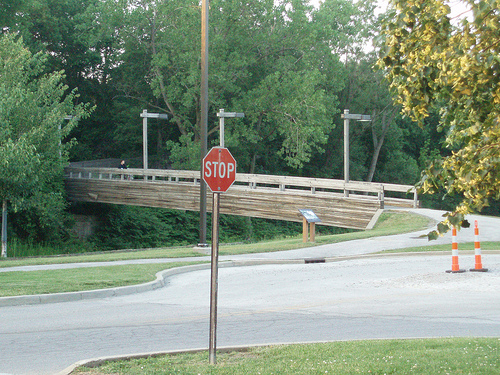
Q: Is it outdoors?
A: Yes, it is outdoors.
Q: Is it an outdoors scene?
A: Yes, it is outdoors.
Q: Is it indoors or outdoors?
A: It is outdoors.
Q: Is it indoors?
A: No, it is outdoors.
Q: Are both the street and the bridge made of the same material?
A: No, the street is made of concrete and the bridge is made of wood.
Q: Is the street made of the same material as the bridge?
A: No, the street is made of concrete and the bridge is made of wood.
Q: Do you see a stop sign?
A: Yes, there is a stop sign.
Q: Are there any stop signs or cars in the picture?
A: Yes, there is a stop sign.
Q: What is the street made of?
A: The street is made of cement.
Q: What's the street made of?
A: The street is made of concrete.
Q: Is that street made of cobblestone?
A: No, the street is made of concrete.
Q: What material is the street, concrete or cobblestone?
A: The street is made of concrete.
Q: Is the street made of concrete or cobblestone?
A: The street is made of concrete.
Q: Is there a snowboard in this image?
A: No, there are no snowboards.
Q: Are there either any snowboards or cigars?
A: No, there are no snowboards or cigars.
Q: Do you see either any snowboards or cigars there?
A: No, there are no snowboards or cigars.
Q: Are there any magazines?
A: No, there are no magazines.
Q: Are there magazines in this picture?
A: No, there are no magazines.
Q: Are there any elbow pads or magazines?
A: No, there are no magazines or elbow pads.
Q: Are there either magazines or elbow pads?
A: No, there are no magazines or elbow pads.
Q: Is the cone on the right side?
A: Yes, the cone is on the right of the image.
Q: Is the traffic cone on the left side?
A: No, the traffic cone is on the right of the image.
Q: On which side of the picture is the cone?
A: The cone is on the right of the image.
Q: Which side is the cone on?
A: The cone is on the right of the image.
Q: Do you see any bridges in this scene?
A: Yes, there is a bridge.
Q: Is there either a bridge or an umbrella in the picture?
A: Yes, there is a bridge.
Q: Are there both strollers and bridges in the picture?
A: No, there is a bridge but no strollers.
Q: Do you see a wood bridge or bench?
A: Yes, there is a wood bridge.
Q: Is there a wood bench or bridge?
A: Yes, there is a wood bridge.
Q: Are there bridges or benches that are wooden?
A: Yes, the bridge is wooden.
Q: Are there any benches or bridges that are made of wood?
A: Yes, the bridge is made of wood.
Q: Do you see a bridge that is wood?
A: Yes, there is a wood bridge.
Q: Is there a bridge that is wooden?
A: Yes, there is a bridge that is wooden.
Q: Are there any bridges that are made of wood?
A: Yes, there is a bridge that is made of wood.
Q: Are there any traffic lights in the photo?
A: No, there are no traffic lights.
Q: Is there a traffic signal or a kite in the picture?
A: No, there are no traffic lights or kites.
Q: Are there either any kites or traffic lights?
A: No, there are no traffic lights or kites.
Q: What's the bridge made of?
A: The bridge is made of wood.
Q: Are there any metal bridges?
A: No, there is a bridge but it is made of wood.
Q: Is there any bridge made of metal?
A: No, there is a bridge but it is made of wood.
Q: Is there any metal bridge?
A: No, there is a bridge but it is made of wood.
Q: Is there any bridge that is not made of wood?
A: No, there is a bridge but it is made of wood.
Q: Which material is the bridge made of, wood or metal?
A: The bridge is made of wood.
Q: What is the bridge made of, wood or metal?
A: The bridge is made of wood.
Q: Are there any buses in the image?
A: No, there are no buses.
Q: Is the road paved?
A: Yes, the road is paved.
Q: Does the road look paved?
A: Yes, the road is paved.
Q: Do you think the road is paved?
A: Yes, the road is paved.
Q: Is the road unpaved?
A: No, the road is paved.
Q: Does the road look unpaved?
A: No, the road is paved.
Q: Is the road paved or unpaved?
A: The road is paved.